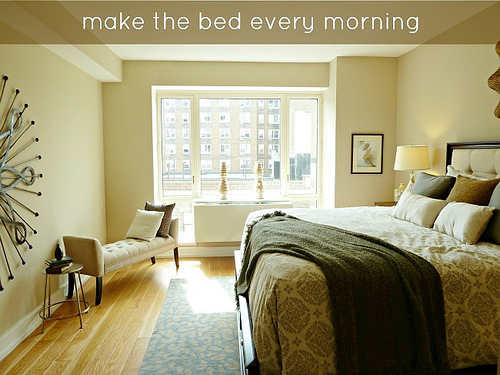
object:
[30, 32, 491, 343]
bedroom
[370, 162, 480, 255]
pillow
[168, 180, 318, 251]
bench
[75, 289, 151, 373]
floor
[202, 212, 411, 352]
spread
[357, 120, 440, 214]
lamp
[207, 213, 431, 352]
banket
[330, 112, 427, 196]
picture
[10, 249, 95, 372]
chair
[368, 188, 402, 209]
table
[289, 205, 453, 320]
comforter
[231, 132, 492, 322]
bed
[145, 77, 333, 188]
view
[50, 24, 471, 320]
room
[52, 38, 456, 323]
hotel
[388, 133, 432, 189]
light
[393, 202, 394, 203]
stand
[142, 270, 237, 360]
rug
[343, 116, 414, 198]
wall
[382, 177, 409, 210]
candle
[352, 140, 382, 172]
image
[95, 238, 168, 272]
couch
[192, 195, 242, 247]
unit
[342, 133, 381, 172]
artwork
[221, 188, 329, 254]
blanket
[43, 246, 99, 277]
book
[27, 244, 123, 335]
stool